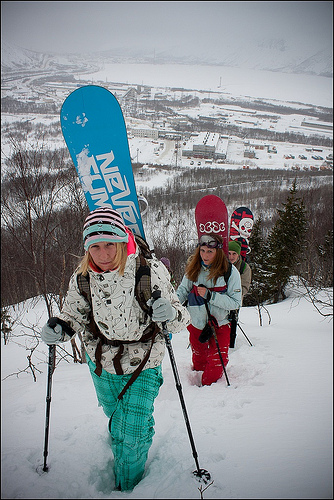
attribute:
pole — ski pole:
[135, 298, 217, 467]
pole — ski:
[39, 340, 55, 474]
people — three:
[71, 221, 258, 403]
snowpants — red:
[186, 321, 232, 386]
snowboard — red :
[55, 65, 190, 456]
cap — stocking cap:
[80, 204, 131, 254]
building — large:
[180, 129, 232, 160]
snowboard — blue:
[27, 54, 206, 417]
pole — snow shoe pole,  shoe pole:
[144, 320, 228, 483]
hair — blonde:
[74, 206, 142, 278]